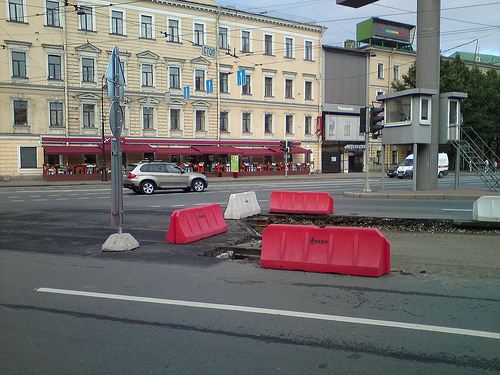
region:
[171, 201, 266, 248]
A red street barrier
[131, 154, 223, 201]
A silver car moving along the roadway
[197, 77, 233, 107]
A blue traffic sign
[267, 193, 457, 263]
An unfinished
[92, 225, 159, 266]
A white concrete base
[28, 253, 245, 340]
A black top street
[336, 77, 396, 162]
An electronic traffic stop and go light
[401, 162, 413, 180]
A small white van.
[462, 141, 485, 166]
Metal staris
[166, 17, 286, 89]
A beige building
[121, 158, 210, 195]
Small beige colored suv.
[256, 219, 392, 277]
Red barrier horizontal to the road.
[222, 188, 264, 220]
A white barrier between two red ones.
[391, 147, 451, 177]
A white van behind a large round pole.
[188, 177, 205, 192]
Black round passenger side front wheel.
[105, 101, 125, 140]
The back of a silver round sign on a pole.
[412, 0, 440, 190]
Very thick round pole that has two small buildings on each side.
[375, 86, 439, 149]
A small two window gray building attached to the front of a pole.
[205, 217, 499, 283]
Rectangular shaped cut out in the road behind the barriers.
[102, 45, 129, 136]
Two top sign backs that are silver on a pole.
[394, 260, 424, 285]
edge of a road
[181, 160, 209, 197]
part of a wheel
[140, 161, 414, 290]
red plastic road barriers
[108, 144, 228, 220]
small compact olive SUV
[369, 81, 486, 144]
large retangle boxes mounted on poll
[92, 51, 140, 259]
set of street signs idicating directional order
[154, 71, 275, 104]
small blue flags with white emblem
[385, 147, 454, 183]
smalle white transport van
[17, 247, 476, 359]
white line lane marker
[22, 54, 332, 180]
beige brick building with burgandy lobby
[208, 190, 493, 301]
section cut out of road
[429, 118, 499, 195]
short set of metal framed stairs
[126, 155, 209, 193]
this is a car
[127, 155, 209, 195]
the car is moving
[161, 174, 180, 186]
the car is grey in color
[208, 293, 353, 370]
this is a road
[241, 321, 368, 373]
the road is tarmacked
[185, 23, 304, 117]
this is a building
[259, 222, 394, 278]
this is a reflector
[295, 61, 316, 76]
the wall is cream in color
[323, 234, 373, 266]
the reflector is red in color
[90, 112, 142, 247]
this is a pole